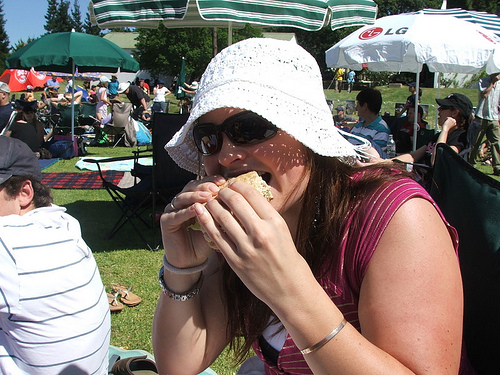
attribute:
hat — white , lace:
[149, 11, 365, 155]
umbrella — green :
[10, 19, 146, 162]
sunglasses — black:
[188, 111, 285, 153]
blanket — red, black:
[38, 169, 125, 191]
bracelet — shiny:
[295, 313, 355, 362]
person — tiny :
[334, 67, 348, 92]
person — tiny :
[347, 65, 359, 95]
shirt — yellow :
[344, 70, 358, 85]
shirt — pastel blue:
[331, 67, 344, 84]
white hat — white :
[152, 34, 369, 186]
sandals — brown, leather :
[107, 276, 144, 309]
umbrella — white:
[323, 8, 495, 79]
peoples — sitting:
[0, 72, 484, 173]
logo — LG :
[342, 13, 439, 55]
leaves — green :
[60, 6, 71, 28]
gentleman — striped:
[0, 136, 109, 373]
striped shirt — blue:
[0, 204, 109, 373]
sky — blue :
[4, 3, 54, 33]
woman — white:
[145, 33, 468, 373]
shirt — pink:
[185, 168, 467, 368]